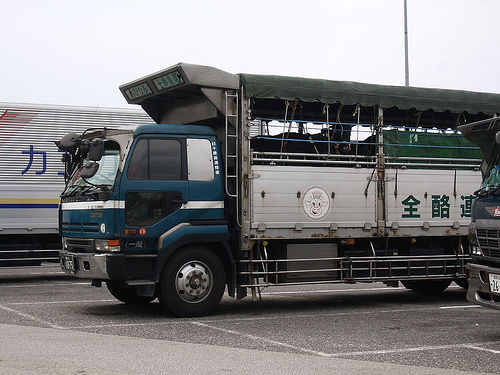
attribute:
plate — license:
[59, 253, 77, 271]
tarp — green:
[234, 72, 499, 134]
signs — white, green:
[117, 69, 189, 102]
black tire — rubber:
[160, 245, 227, 316]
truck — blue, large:
[52, 59, 497, 314]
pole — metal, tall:
[403, 0, 410, 87]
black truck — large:
[87, 64, 465, 314]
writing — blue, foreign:
[17, 143, 51, 183]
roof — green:
[236, 70, 498, 115]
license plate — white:
[486, 272, 498, 297]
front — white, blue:
[44, 117, 239, 309]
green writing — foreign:
[407, 190, 477, 223]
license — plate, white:
[487, 268, 498, 297]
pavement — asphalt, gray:
[4, 265, 493, 364]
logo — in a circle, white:
[299, 186, 333, 221]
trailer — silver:
[201, 68, 485, 285]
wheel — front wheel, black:
[157, 235, 233, 318]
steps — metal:
[239, 235, 469, 286]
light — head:
[82, 232, 113, 260]